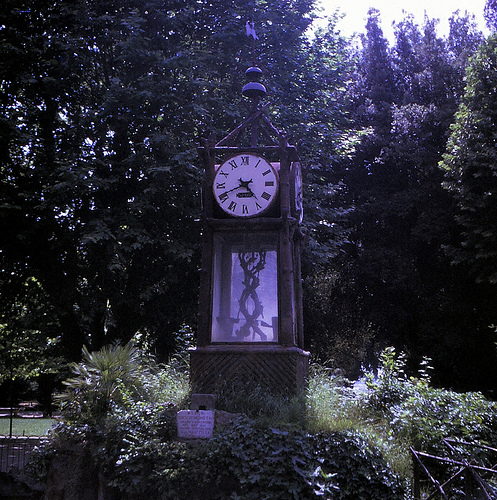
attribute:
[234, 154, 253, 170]
roman numeral —  number 12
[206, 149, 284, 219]
clock — white, black, outdoors, foundation 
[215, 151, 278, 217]
clock — large 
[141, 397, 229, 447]
sign — small 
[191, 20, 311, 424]
clock — right sided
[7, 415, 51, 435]
lawn — green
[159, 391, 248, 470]
sign — stone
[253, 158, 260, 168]
number 1 — roman numeral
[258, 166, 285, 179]
roman numeral — 2, number 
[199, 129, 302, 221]
clock — top piece 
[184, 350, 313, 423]
base — concrete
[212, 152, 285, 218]
clock face — black , white 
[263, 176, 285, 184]
number — 3, roman numeral 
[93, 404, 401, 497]
ivy — green , section 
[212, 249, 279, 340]
glass — seen through 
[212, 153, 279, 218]
face — white